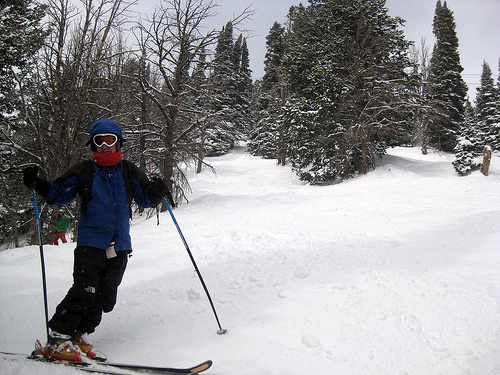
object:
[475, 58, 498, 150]
tree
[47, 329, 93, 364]
boots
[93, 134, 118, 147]
goggles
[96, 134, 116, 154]
face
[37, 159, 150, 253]
jacket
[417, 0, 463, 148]
tree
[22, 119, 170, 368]
woman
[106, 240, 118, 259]
tag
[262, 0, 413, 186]
tree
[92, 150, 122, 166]
scarf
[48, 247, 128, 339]
black pants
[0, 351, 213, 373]
skiis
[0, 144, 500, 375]
ground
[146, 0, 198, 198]
trees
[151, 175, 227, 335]
ski poles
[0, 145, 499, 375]
snow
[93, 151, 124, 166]
neck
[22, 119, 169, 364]
he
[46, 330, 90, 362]
feet